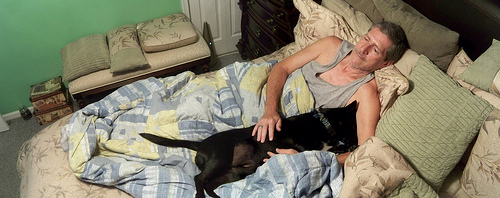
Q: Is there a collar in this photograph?
A: Yes, there is a collar.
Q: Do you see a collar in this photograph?
A: Yes, there is a collar.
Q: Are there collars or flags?
A: Yes, there is a collar.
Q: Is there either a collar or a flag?
A: Yes, there is a collar.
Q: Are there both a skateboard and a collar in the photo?
A: No, there is a collar but no skateboards.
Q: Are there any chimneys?
A: No, there are no chimneys.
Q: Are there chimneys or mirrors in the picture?
A: No, there are no chimneys or mirrors.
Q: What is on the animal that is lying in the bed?
A: The collar is on the dog.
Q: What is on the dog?
A: The collar is on the dog.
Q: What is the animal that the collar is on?
A: The animal is a dog.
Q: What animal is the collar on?
A: The collar is on the dog.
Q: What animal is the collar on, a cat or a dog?
A: The collar is on a dog.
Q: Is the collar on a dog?
A: Yes, the collar is on a dog.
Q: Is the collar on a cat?
A: No, the collar is on a dog.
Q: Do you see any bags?
A: No, there are no bags.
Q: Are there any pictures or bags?
A: No, there are no bags or pictures.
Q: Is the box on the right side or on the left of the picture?
A: The box is on the left of the image.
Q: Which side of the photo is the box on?
A: The box is on the left of the image.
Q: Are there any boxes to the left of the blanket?
A: Yes, there is a box to the left of the blanket.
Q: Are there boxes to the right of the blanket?
A: No, the box is to the left of the blanket.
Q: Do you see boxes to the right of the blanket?
A: No, the box is to the left of the blanket.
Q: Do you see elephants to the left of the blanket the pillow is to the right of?
A: No, there is a box to the left of the blanket.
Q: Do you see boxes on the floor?
A: Yes, there is a box on the floor.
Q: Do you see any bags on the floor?
A: No, there is a box on the floor.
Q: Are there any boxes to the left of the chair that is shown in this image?
A: Yes, there is a box to the left of the chair.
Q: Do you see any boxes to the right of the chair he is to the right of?
A: No, the box is to the left of the chair.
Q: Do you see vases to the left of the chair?
A: No, there is a box to the left of the chair.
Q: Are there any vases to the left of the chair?
A: No, there is a box to the left of the chair.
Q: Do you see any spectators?
A: No, there are no spectators.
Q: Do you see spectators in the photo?
A: No, there are no spectators.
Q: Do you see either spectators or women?
A: No, there are no spectators or women.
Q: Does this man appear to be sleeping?
A: Yes, the man is sleeping.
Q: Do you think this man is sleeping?
A: Yes, the man is sleeping.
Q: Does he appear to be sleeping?
A: Yes, the man is sleeping.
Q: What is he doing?
A: The man is sleeping.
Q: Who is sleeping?
A: The man is sleeping.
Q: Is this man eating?
A: No, the man is sleeping.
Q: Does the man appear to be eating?
A: No, the man is sleeping.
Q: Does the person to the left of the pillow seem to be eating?
A: No, the man is sleeping.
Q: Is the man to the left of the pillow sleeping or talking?
A: The man is sleeping.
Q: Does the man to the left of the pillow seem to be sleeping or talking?
A: The man is sleeping.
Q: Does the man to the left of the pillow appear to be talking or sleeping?
A: The man is sleeping.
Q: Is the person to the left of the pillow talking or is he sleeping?
A: The man is sleeping.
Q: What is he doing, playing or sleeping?
A: The man is sleeping.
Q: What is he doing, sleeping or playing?
A: The man is sleeping.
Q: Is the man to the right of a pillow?
A: No, the man is to the left of a pillow.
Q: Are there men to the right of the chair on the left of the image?
A: Yes, there is a man to the right of the chair.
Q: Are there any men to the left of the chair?
A: No, the man is to the right of the chair.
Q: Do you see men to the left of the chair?
A: No, the man is to the right of the chair.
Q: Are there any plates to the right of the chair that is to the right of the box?
A: No, there is a man to the right of the chair.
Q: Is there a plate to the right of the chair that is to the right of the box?
A: No, there is a man to the right of the chair.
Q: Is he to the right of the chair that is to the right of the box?
A: Yes, the man is to the right of the chair.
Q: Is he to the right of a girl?
A: No, the man is to the right of the chair.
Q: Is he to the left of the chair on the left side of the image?
A: No, the man is to the right of the chair.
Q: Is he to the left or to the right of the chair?
A: The man is to the right of the chair.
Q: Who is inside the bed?
A: The man is inside the bed.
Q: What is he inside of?
A: The man is inside the bed.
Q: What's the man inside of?
A: The man is inside the bed.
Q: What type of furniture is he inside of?
A: The man is inside the bed.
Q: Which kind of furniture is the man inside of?
A: The man is inside the bed.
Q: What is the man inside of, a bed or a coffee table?
A: The man is inside a bed.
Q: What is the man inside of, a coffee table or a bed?
A: The man is inside a bed.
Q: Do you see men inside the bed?
A: Yes, there is a man inside the bed.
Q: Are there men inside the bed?
A: Yes, there is a man inside the bed.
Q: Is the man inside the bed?
A: Yes, the man is inside the bed.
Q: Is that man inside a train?
A: No, the man is inside the bed.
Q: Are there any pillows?
A: Yes, there is a pillow.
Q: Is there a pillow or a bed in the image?
A: Yes, there is a pillow.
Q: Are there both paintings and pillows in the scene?
A: No, there is a pillow but no paintings.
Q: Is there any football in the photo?
A: No, there are no footballs.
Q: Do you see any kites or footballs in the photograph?
A: No, there are no footballs or kites.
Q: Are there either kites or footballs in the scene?
A: No, there are no footballs or kites.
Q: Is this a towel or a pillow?
A: This is a pillow.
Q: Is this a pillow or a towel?
A: This is a pillow.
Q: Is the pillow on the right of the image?
A: Yes, the pillow is on the right of the image.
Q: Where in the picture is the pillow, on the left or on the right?
A: The pillow is on the right of the image.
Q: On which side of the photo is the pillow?
A: The pillow is on the right of the image.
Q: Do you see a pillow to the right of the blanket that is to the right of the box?
A: Yes, there is a pillow to the right of the blanket.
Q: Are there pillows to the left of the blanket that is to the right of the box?
A: No, the pillow is to the right of the blanket.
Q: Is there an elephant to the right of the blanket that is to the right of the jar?
A: No, there is a pillow to the right of the blanket.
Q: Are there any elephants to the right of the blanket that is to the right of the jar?
A: No, there is a pillow to the right of the blanket.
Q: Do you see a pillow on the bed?
A: Yes, there is a pillow on the bed.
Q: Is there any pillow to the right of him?
A: Yes, there is a pillow to the right of the man.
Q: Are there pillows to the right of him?
A: Yes, there is a pillow to the right of the man.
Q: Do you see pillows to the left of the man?
A: No, the pillow is to the right of the man.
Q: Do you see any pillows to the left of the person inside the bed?
A: No, the pillow is to the right of the man.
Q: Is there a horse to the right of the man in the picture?
A: No, there is a pillow to the right of the man.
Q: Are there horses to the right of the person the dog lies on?
A: No, there is a pillow to the right of the man.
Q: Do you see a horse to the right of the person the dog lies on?
A: No, there is a pillow to the right of the man.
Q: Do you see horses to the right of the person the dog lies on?
A: No, there is a pillow to the right of the man.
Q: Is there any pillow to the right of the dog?
A: Yes, there is a pillow to the right of the dog.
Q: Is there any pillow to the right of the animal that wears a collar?
A: Yes, there is a pillow to the right of the dog.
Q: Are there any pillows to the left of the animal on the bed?
A: No, the pillow is to the right of the dog.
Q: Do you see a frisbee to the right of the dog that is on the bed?
A: No, there is a pillow to the right of the dog.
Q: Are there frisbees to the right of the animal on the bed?
A: No, there is a pillow to the right of the dog.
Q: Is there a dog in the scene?
A: Yes, there is a dog.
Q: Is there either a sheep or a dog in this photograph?
A: Yes, there is a dog.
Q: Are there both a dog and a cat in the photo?
A: No, there is a dog but no cats.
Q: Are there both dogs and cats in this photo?
A: No, there is a dog but no cats.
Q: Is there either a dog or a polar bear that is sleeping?
A: Yes, the dog is sleeping.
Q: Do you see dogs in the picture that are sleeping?
A: Yes, there is a dog that is sleeping.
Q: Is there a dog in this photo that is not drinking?
A: Yes, there is a dog that is sleeping.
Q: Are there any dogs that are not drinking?
A: Yes, there is a dog that is sleeping.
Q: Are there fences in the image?
A: No, there are no fences.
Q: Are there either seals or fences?
A: No, there are no fences or seals.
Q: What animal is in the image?
A: The animal is a dog.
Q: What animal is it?
A: The animal is a dog.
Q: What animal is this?
A: That is a dog.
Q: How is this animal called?
A: That is a dog.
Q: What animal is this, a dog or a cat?
A: That is a dog.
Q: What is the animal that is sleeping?
A: The animal is a dog.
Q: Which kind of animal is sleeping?
A: The animal is a dog.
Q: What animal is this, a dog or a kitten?
A: This is a dog.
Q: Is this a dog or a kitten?
A: This is a dog.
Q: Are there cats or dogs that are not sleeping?
A: No, there is a dog but it is sleeping.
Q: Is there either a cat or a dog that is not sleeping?
A: No, there is a dog but it is sleeping.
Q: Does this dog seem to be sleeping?
A: Yes, the dog is sleeping.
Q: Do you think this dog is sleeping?
A: Yes, the dog is sleeping.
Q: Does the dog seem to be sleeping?
A: Yes, the dog is sleeping.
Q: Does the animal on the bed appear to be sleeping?
A: Yes, the dog is sleeping.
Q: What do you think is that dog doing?
A: The dog is sleeping.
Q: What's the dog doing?
A: The dog is sleeping.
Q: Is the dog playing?
A: No, the dog is sleeping.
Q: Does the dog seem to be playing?
A: No, the dog is sleeping.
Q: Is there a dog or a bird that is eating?
A: No, there is a dog but it is sleeping.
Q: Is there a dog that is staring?
A: No, there is a dog but it is sleeping.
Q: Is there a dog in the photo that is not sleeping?
A: No, there is a dog but it is sleeping.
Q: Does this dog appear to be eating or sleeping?
A: The dog is sleeping.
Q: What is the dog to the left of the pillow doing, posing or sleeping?
A: The dog is sleeping.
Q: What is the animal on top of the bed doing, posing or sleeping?
A: The dog is sleeping.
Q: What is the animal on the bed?
A: The animal is a dog.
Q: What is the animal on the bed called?
A: The animal is a dog.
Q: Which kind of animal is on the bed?
A: The animal is a dog.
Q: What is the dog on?
A: The dog is on the bed.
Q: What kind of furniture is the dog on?
A: The dog is on the bed.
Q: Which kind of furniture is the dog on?
A: The dog is on the bed.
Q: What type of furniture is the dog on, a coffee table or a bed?
A: The dog is on a bed.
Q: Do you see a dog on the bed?
A: Yes, there is a dog on the bed.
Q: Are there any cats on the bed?
A: No, there is a dog on the bed.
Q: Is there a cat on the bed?
A: No, there is a dog on the bed.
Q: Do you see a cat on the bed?
A: No, there is a dog on the bed.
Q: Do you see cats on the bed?
A: No, there is a dog on the bed.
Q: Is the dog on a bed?
A: Yes, the dog is on a bed.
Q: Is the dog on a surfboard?
A: No, the dog is on a bed.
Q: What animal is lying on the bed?
A: The dog is lying on the bed.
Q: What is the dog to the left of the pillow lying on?
A: The dog is lying on the bed.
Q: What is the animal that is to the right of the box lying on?
A: The dog is lying on the bed.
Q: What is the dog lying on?
A: The dog is lying on the bed.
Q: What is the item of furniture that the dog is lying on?
A: The piece of furniture is a bed.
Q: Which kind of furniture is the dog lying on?
A: The dog is lying on the bed.